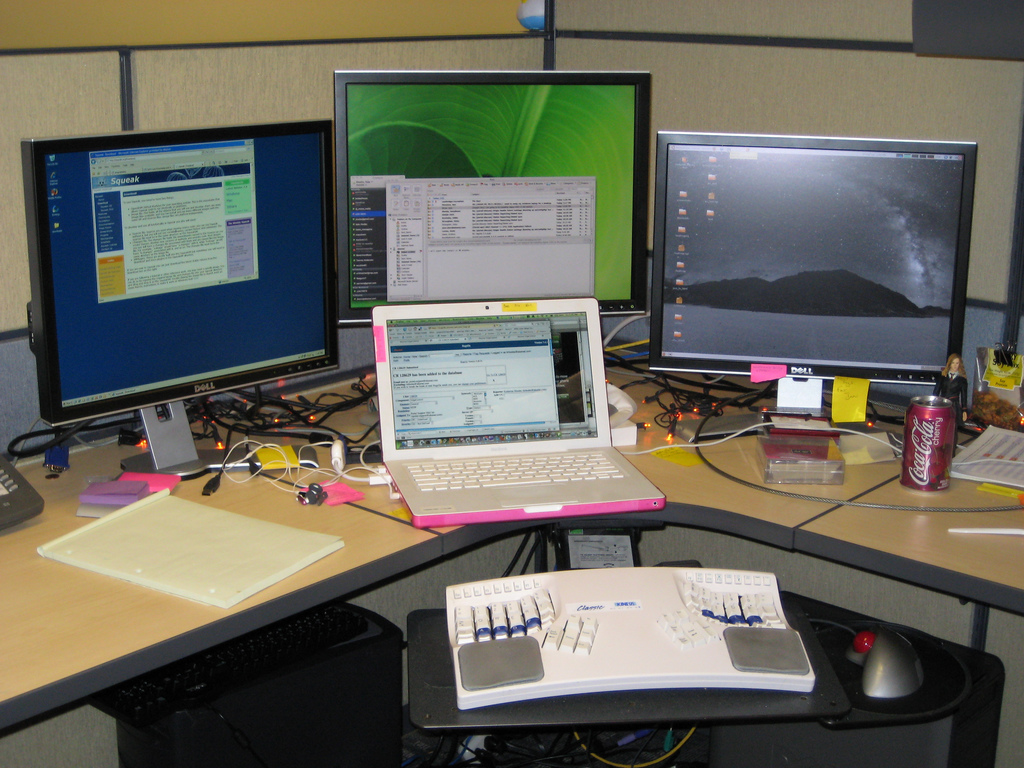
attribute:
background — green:
[349, 80, 657, 306]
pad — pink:
[295, 476, 368, 505]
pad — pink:
[118, 469, 182, 490]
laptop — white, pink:
[369, 292, 667, 528]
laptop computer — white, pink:
[351, 285, 781, 565]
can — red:
[901, 395, 956, 491]